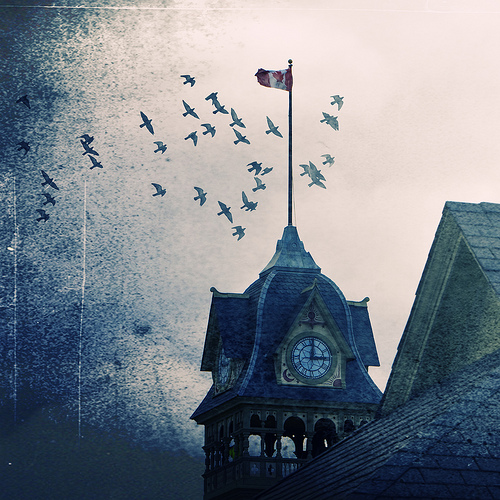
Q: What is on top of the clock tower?
A: A flag pole.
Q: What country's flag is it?
A: Canada.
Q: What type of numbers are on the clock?
A: Roman numerals.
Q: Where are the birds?
A: Flying near the flagpole.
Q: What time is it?
A: 3:00.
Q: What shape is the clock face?
A: A circle.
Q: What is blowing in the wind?
A: The flag.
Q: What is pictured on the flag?
A: A leaf.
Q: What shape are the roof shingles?
A: Rectangular.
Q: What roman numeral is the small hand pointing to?
A: III.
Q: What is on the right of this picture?
A: The roof of a building.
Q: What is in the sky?
A: A flock of birds.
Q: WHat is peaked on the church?
A: The roof.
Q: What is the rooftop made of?
A: Shingle.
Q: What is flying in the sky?
A: Several birds.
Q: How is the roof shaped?
A: Like a triangle.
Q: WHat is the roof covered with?
A: The roof is covered with gray shingles.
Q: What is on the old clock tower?
A: A flag.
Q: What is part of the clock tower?
A: A viewing area.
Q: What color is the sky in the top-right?
A: White.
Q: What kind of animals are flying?
A: Birds.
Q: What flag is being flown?
A: A Canadian flag.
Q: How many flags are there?
A: One.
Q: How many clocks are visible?
A: Two.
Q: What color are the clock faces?
A: White.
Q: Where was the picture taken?
A: At a church.